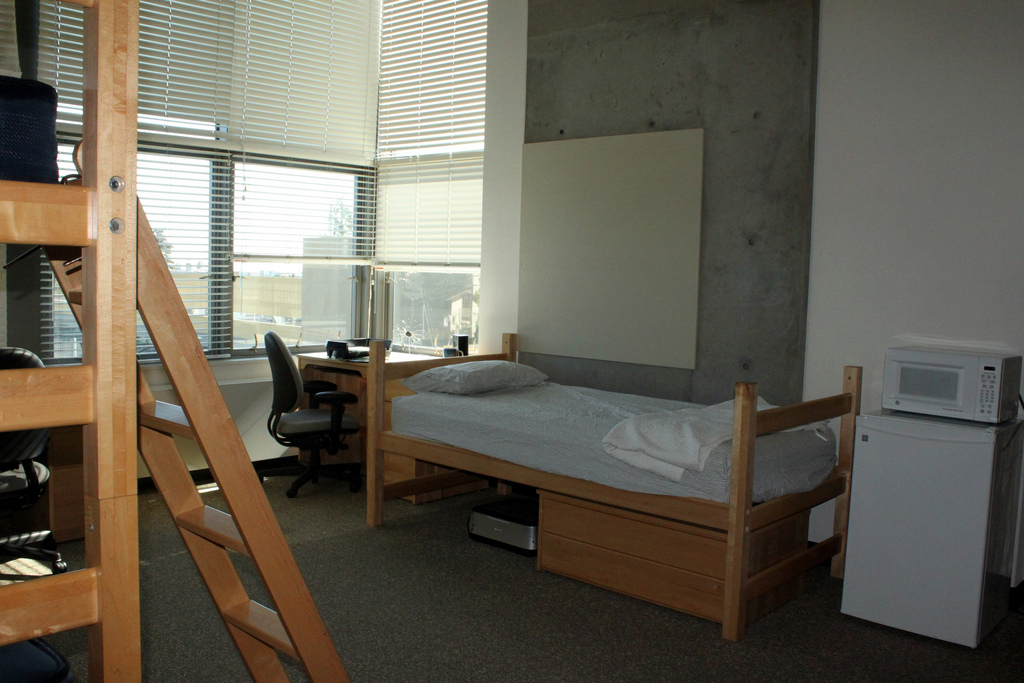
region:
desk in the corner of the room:
[287, 316, 415, 472]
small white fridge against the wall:
[831, 417, 997, 642]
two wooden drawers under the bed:
[508, 490, 742, 650]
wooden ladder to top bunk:
[122, 209, 338, 668]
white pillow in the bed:
[433, 357, 538, 396]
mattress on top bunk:
[5, 64, 62, 170]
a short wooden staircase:
[44, 144, 346, 680]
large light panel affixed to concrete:
[514, 1, 822, 409]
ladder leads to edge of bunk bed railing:
[3, 1, 348, 681]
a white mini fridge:
[836, 411, 1021, 649]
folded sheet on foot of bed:
[359, 329, 857, 640]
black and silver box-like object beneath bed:
[359, 330, 859, 637]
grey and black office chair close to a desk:
[262, 331, 446, 502]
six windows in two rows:
[50, 2, 490, 361]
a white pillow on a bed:
[399, 354, 559, 402]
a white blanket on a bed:
[582, 382, 805, 499]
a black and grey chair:
[248, 324, 366, 499]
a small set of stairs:
[22, 142, 358, 680]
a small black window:
[222, 156, 378, 356]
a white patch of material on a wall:
[506, 125, 707, 375]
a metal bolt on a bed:
[108, 173, 121, 194]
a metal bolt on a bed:
[107, 208, 126, 235]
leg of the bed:
[738, 591, 757, 615]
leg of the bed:
[829, 537, 843, 596]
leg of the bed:
[352, 490, 391, 517]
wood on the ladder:
[247, 612, 299, 642]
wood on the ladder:
[27, 574, 110, 622]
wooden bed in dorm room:
[359, 347, 863, 642]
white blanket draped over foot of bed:
[588, 388, 801, 481]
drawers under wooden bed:
[529, 493, 839, 631]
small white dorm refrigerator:
[830, 404, 996, 661]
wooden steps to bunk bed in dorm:
[40, 187, 367, 678]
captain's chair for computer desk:
[254, 332, 362, 498]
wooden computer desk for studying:
[304, 334, 479, 497]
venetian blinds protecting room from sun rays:
[0, 0, 490, 363]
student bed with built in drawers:
[377, 341, 858, 662]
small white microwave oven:
[880, 329, 1002, 428]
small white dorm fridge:
[833, 414, 1014, 645]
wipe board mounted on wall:
[510, 133, 711, 371]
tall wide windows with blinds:
[0, 0, 488, 349]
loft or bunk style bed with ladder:
[0, 1, 302, 678]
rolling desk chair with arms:
[251, 333, 360, 492]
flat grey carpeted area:
[93, 529, 1021, 679]